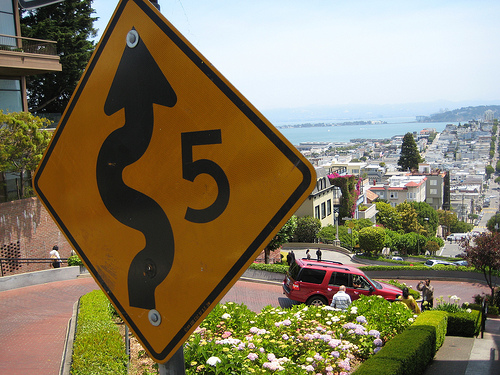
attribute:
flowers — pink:
[208, 304, 398, 372]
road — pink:
[0, 278, 499, 375]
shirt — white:
[49, 246, 61, 260]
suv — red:
[279, 254, 403, 311]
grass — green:
[69, 291, 123, 374]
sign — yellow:
[30, 0, 333, 367]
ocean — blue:
[283, 123, 471, 149]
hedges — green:
[328, 302, 485, 373]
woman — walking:
[43, 241, 61, 267]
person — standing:
[416, 275, 439, 313]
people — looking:
[303, 245, 323, 261]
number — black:
[163, 119, 238, 228]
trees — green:
[262, 199, 461, 262]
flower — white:
[207, 355, 223, 370]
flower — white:
[250, 325, 267, 339]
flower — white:
[218, 337, 244, 349]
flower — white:
[263, 352, 284, 369]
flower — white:
[346, 322, 366, 336]